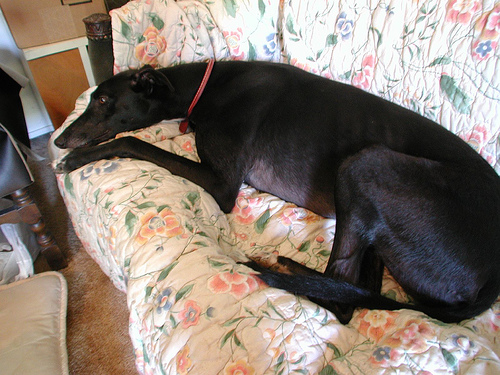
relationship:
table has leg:
[0, 68, 68, 271] [12, 186, 68, 271]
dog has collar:
[53, 59, 500, 325] [180, 60, 215, 136]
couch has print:
[48, 1, 500, 374] [439, 71, 471, 116]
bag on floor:
[0, 223, 42, 287] [0, 128, 140, 374]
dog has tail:
[53, 59, 500, 325] [254, 274, 420, 310]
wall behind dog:
[1, 0, 106, 131] [53, 59, 500, 325]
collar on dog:
[180, 60, 215, 136] [53, 59, 500, 325]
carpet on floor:
[0, 134, 142, 374] [0, 128, 140, 374]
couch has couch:
[48, 1, 500, 374] [48, 1, 500, 374]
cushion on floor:
[0, 270, 70, 374] [0, 128, 140, 374]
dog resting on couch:
[53, 59, 500, 325] [48, 1, 500, 374]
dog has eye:
[53, 59, 500, 325] [97, 93, 110, 104]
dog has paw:
[53, 59, 500, 325] [55, 151, 82, 173]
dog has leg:
[53, 59, 500, 325] [276, 238, 369, 324]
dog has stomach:
[53, 59, 500, 325] [242, 156, 336, 218]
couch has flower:
[48, 1, 500, 374] [352, 56, 375, 92]